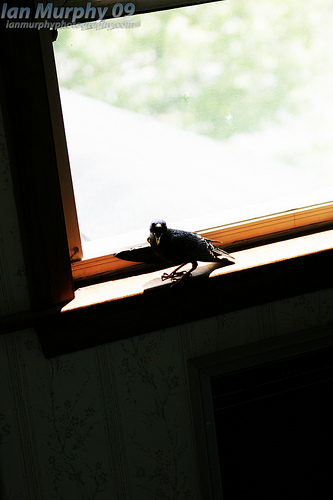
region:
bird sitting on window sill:
[141, 215, 236, 293]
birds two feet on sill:
[156, 270, 195, 289]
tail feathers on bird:
[208, 244, 238, 262]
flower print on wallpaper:
[122, 341, 178, 434]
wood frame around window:
[22, 115, 56, 267]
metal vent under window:
[184, 345, 279, 424]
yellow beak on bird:
[152, 224, 167, 246]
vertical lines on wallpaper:
[102, 353, 112, 455]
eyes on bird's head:
[149, 221, 168, 228]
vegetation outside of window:
[164, 38, 272, 106]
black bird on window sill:
[121, 220, 244, 280]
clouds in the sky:
[115, 46, 268, 119]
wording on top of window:
[1, 3, 157, 38]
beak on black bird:
[155, 235, 166, 242]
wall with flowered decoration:
[44, 393, 153, 475]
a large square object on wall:
[175, 339, 331, 495]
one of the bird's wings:
[114, 249, 162, 267]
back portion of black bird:
[192, 234, 237, 265]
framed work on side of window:
[8, 149, 59, 186]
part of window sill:
[253, 240, 301, 257]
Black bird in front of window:
[141, 213, 239, 281]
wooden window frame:
[19, 207, 77, 356]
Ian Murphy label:
[0, 0, 142, 33]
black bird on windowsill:
[127, 193, 278, 289]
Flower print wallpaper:
[63, 386, 182, 490]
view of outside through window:
[96, 41, 318, 175]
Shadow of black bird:
[130, 260, 232, 292]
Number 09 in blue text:
[109, 0, 133, 18]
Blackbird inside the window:
[131, 202, 242, 284]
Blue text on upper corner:
[0, 0, 143, 33]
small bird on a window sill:
[144, 218, 235, 283]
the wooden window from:
[4, 0, 331, 360]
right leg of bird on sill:
[169, 262, 187, 273]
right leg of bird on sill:
[185, 260, 198, 274]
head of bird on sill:
[144, 220, 167, 245]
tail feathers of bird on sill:
[206, 237, 235, 263]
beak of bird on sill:
[152, 233, 163, 243]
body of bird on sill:
[156, 230, 195, 260]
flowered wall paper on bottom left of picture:
[3, 328, 198, 499]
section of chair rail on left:
[1, 307, 32, 342]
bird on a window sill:
[126, 211, 231, 297]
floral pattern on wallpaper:
[116, 335, 190, 491]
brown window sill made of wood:
[22, 226, 319, 362]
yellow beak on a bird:
[149, 233, 167, 250]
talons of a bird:
[156, 261, 205, 288]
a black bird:
[126, 209, 243, 301]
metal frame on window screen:
[35, 23, 92, 268]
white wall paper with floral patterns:
[8, 338, 211, 493]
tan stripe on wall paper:
[90, 338, 137, 498]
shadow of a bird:
[135, 269, 222, 313]